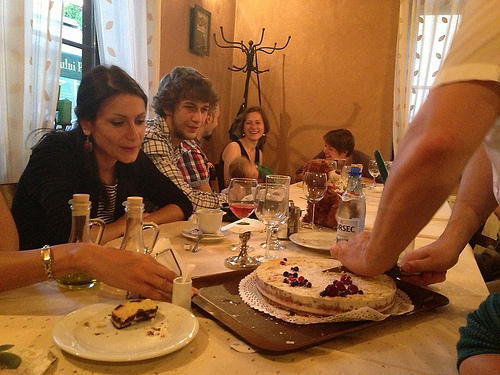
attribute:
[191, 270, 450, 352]
tray — brown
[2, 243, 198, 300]
hand — part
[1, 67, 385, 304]
family — sitting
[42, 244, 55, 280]
watch — silver, thin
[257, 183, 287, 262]
wine glass — empty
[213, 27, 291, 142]
coat rack — black, dark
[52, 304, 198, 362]
plate — white, round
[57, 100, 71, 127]
candle — green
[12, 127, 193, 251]
shirt — black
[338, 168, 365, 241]
bottled water — clear, blue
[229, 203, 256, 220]
wine — pink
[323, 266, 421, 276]
knife — silver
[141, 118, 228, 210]
shirt — black, plaid shirt, white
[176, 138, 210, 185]
shirt — plaid shirt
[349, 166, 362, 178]
bottle cap — blue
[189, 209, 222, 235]
cup — white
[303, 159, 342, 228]
toy — brown